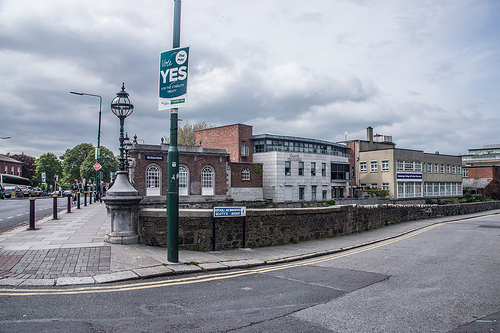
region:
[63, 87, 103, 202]
lamp with post in the side walk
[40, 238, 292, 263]
side walk with the post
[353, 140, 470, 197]
big building with lot of windows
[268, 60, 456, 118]
sky with clouds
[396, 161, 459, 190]
lot of windows in the building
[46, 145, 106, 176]
trees with branches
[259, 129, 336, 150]
top of the building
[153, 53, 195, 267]
metal post with some advertisement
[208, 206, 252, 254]
a board with post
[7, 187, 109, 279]
road with side walk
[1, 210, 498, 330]
A road by the sidewalk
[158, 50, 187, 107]
A political sign on the post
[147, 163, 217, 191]
Windows on the building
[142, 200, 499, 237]
A wall by the sidewalk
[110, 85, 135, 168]
A lamp post above the sidewalk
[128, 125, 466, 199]
Buildings behind the political sign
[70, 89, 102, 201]
A lamp post near the buildings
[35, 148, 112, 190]
Green trees behind the buildings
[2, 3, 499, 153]
A cloudy sky above the buildings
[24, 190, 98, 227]
Black posts along the sidewalk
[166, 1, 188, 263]
green metal post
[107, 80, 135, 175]
black metal street lamp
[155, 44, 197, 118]
green and white sign with the word "yes"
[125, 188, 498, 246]
short stone wall running near the sidewalk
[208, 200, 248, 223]
blue and white sign on the stone wall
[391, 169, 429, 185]
blue and white sign on a tan building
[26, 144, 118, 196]
green trees at the end of a tree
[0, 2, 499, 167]
blue sky with clouds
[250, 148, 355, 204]
white brick building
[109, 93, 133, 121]
globe on a lamp post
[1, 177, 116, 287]
a concrete sidewalk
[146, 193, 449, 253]
a rock wall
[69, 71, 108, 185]
a tall street light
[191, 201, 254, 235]
a blue and white sign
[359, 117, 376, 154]
a chimney on top of a building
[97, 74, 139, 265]
a street light with a concrete base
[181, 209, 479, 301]
a sidewalk next to a street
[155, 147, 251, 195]
a red brick building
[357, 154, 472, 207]
a building with a blue and white sign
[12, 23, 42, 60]
white clouds in blue sky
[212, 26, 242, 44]
white clouds in blue sky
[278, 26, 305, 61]
white clouds in blue sky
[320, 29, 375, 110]
white clouds in blue sky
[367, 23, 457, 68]
white clouds in blue sky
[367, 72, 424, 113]
white clouds in blue sky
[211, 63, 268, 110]
white clouds in blue sky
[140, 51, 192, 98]
green and white sign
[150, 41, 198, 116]
white and green sign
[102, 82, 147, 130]
street lamp